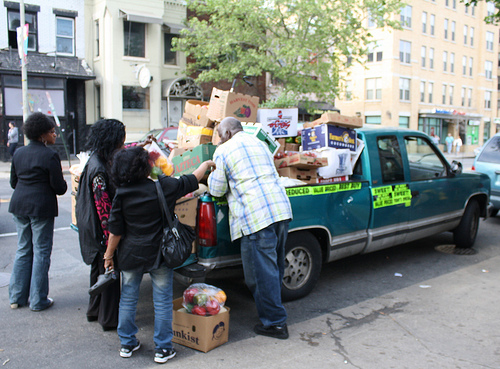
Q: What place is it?
A: It is a street.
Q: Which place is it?
A: It is a street.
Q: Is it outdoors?
A: Yes, it is outdoors.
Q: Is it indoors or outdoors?
A: It is outdoors.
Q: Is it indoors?
A: No, it is outdoors.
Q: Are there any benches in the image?
A: No, there are no benches.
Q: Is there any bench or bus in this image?
A: No, there are no benches or buses.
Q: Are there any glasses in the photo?
A: No, there are no glasses.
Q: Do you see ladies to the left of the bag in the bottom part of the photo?
A: Yes, there is a lady to the left of the bag.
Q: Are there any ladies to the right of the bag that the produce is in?
A: No, the lady is to the left of the bag.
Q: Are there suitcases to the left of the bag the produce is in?
A: No, there is a lady to the left of the bag.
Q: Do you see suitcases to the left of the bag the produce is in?
A: No, there is a lady to the left of the bag.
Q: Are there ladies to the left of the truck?
A: Yes, there is a lady to the left of the truck.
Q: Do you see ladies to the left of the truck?
A: Yes, there is a lady to the left of the truck.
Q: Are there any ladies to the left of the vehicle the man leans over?
A: Yes, there is a lady to the left of the truck.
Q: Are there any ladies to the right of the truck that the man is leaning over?
A: No, the lady is to the left of the truck.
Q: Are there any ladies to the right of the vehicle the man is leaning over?
A: No, the lady is to the left of the truck.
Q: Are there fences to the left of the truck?
A: No, there is a lady to the left of the truck.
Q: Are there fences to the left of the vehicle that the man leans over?
A: No, there is a lady to the left of the truck.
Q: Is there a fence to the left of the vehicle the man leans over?
A: No, there is a lady to the left of the truck.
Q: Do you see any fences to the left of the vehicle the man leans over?
A: No, there is a lady to the left of the truck.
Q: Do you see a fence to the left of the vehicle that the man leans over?
A: No, there is a lady to the left of the truck.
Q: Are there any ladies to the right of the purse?
A: No, the lady is to the left of the purse.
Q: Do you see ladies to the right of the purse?
A: No, the lady is to the left of the purse.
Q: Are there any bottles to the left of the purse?
A: No, there is a lady to the left of the purse.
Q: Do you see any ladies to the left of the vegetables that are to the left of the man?
A: Yes, there is a lady to the left of the veggies.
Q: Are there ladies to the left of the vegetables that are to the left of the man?
A: Yes, there is a lady to the left of the veggies.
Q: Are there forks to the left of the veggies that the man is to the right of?
A: No, there is a lady to the left of the vegetables.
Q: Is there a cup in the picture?
A: No, there are no cups.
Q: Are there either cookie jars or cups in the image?
A: No, there are no cups or cookie jars.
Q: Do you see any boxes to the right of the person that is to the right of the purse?
A: Yes, there is a box to the right of the man.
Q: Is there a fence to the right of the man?
A: No, there is a box to the right of the man.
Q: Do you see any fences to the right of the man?
A: No, there is a box to the right of the man.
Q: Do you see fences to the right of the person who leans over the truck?
A: No, there is a box to the right of the man.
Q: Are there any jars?
A: No, there are no jars.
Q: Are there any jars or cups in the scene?
A: No, there are no jars or cups.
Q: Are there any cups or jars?
A: No, there are no jars or cups.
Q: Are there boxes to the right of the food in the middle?
A: Yes, there is a box to the right of the food.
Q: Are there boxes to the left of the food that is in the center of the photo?
A: No, the box is to the right of the food.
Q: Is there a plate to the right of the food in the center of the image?
A: No, there is a box to the right of the food.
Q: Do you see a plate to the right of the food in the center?
A: No, there is a box to the right of the food.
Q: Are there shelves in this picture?
A: No, there are no shelves.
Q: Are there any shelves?
A: No, there are no shelves.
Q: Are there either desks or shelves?
A: No, there are no shelves or desks.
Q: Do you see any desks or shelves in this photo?
A: No, there are no shelves or desks.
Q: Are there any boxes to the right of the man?
A: Yes, there is a box to the right of the man.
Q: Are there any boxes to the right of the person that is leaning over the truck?
A: Yes, there is a box to the right of the man.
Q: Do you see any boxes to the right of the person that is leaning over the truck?
A: Yes, there is a box to the right of the man.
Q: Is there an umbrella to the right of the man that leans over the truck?
A: No, there is a box to the right of the man.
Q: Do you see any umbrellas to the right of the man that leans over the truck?
A: No, there is a box to the right of the man.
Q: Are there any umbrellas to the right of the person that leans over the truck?
A: No, there is a box to the right of the man.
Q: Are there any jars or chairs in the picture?
A: No, there are no jars or chairs.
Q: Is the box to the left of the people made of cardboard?
A: Yes, the box is made of cardboard.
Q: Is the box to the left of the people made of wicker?
A: No, the box is made of cardboard.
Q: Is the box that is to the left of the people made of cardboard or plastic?
A: The box is made of cardboard.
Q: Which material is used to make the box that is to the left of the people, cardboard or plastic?
A: The box is made of cardboard.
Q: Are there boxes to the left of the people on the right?
A: Yes, there is a box to the left of the people.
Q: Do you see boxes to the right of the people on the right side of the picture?
A: No, the box is to the left of the people.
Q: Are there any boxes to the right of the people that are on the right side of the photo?
A: No, the box is to the left of the people.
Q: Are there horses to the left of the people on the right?
A: No, there is a box to the left of the people.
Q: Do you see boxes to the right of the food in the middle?
A: Yes, there is a box to the right of the food.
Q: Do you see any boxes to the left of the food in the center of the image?
A: No, the box is to the right of the food.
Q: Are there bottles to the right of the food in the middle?
A: No, there is a box to the right of the food.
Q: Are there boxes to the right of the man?
A: Yes, there is a box to the right of the man.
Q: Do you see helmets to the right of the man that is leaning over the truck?
A: No, there is a box to the right of the man.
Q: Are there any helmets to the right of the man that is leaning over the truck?
A: No, there is a box to the right of the man.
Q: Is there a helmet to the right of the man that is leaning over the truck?
A: No, there is a box to the right of the man.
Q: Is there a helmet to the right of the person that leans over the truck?
A: No, there is a box to the right of the man.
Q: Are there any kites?
A: No, there are no kites.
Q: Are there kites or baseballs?
A: No, there are no kites or baseballs.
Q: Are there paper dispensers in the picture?
A: No, there are no paper dispensers.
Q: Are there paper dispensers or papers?
A: No, there are no paper dispensers or papers.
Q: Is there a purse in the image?
A: Yes, there is a purse.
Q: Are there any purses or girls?
A: Yes, there is a purse.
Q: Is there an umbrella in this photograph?
A: No, there are no umbrellas.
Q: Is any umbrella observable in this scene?
A: No, there are no umbrellas.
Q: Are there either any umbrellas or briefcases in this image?
A: No, there are no umbrellas or briefcases.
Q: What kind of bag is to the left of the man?
A: The bag is a purse.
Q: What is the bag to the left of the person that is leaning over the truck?
A: The bag is a purse.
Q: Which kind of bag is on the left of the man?
A: The bag is a purse.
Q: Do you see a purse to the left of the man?
A: Yes, there is a purse to the left of the man.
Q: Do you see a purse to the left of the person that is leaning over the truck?
A: Yes, there is a purse to the left of the man.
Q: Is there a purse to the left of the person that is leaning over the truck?
A: Yes, there is a purse to the left of the man.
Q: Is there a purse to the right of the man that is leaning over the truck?
A: No, the purse is to the left of the man.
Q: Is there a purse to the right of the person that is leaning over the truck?
A: No, the purse is to the left of the man.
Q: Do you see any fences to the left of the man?
A: No, there is a purse to the left of the man.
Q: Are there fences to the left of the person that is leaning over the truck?
A: No, there is a purse to the left of the man.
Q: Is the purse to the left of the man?
A: Yes, the purse is to the left of the man.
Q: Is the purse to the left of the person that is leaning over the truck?
A: Yes, the purse is to the left of the man.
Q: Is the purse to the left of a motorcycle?
A: No, the purse is to the left of the man.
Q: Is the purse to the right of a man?
A: No, the purse is to the left of a man.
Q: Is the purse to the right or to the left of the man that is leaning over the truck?
A: The purse is to the left of the man.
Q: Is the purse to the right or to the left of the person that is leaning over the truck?
A: The purse is to the left of the man.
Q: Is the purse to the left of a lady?
A: No, the purse is to the right of a lady.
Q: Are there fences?
A: No, there are no fences.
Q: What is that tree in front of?
A: The tree is in front of the building.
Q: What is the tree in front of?
A: The tree is in front of the building.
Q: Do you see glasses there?
A: No, there are no glasses.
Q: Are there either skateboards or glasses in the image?
A: No, there are no glasses or skateboards.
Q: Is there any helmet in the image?
A: No, there are no helmets.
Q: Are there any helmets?
A: No, there are no helmets.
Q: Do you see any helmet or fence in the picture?
A: No, there are no helmets or fences.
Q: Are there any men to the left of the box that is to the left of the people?
A: Yes, there is a man to the left of the box.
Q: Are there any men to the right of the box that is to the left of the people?
A: No, the man is to the left of the box.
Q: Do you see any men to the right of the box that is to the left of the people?
A: No, the man is to the left of the box.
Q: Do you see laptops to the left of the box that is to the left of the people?
A: No, there is a man to the left of the box.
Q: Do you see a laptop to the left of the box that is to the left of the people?
A: No, there is a man to the left of the box.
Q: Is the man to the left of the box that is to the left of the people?
A: Yes, the man is to the left of the box.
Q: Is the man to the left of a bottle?
A: No, the man is to the left of the box.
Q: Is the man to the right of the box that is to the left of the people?
A: No, the man is to the left of the box.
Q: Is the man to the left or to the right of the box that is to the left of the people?
A: The man is to the left of the box.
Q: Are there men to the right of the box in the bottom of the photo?
A: Yes, there is a man to the right of the box.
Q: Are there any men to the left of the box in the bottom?
A: No, the man is to the right of the box.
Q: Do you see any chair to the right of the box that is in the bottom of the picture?
A: No, there is a man to the right of the box.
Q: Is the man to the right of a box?
A: Yes, the man is to the right of a box.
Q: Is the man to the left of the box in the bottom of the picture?
A: No, the man is to the right of the box.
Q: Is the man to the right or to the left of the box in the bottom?
A: The man is to the right of the box.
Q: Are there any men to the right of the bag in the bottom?
A: Yes, there is a man to the right of the bag.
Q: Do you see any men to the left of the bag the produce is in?
A: No, the man is to the right of the bag.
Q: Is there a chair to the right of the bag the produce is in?
A: No, there is a man to the right of the bag.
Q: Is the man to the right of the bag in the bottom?
A: Yes, the man is to the right of the bag.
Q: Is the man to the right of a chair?
A: No, the man is to the right of the bag.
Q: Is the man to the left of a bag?
A: No, the man is to the right of a bag.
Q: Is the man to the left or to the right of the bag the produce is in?
A: The man is to the right of the bag.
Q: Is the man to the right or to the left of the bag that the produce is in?
A: The man is to the right of the bag.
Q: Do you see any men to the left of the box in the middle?
A: Yes, there is a man to the left of the box.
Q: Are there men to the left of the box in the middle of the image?
A: Yes, there is a man to the left of the box.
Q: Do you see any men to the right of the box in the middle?
A: No, the man is to the left of the box.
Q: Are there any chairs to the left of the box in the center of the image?
A: No, there is a man to the left of the box.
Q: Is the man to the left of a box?
A: Yes, the man is to the left of a box.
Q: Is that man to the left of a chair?
A: No, the man is to the left of a box.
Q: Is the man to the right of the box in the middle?
A: No, the man is to the left of the box.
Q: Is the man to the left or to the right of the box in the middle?
A: The man is to the left of the box.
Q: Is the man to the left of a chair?
A: No, the man is to the left of a box.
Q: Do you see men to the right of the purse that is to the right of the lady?
A: Yes, there is a man to the right of the purse.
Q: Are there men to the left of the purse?
A: No, the man is to the right of the purse.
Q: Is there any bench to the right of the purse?
A: No, there is a man to the right of the purse.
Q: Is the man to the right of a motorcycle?
A: No, the man is to the right of the purse.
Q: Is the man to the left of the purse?
A: No, the man is to the right of the purse.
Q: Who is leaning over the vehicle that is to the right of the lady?
A: The man is leaning over the truck.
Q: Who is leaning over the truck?
A: The man is leaning over the truck.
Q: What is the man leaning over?
A: The man is leaning over the truck.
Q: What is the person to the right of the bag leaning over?
A: The man is leaning over the truck.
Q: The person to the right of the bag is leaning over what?
A: The man is leaning over the truck.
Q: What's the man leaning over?
A: The man is leaning over the truck.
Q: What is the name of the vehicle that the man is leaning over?
A: The vehicle is a truck.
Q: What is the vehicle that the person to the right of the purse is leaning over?
A: The vehicle is a truck.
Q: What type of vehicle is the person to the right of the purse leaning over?
A: The man is leaning over the truck.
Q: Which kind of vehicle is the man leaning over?
A: The man is leaning over the truck.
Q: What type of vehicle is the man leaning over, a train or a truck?
A: The man is leaning over a truck.